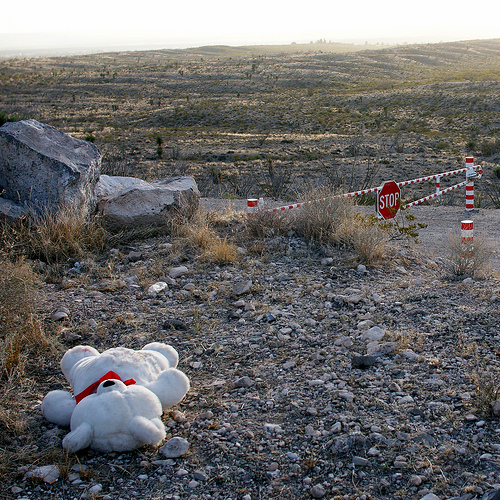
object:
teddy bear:
[36, 340, 189, 454]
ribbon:
[75, 374, 142, 402]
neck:
[75, 371, 156, 405]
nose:
[98, 378, 118, 390]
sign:
[376, 181, 405, 220]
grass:
[174, 210, 237, 266]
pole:
[462, 155, 477, 213]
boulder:
[3, 115, 105, 223]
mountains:
[4, 2, 496, 213]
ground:
[3, 226, 498, 499]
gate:
[245, 157, 478, 232]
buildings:
[311, 35, 344, 49]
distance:
[5, 3, 499, 69]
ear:
[127, 417, 182, 447]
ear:
[62, 421, 95, 453]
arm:
[150, 365, 191, 419]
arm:
[40, 389, 80, 424]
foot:
[142, 340, 181, 369]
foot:
[55, 342, 97, 370]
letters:
[378, 190, 402, 211]